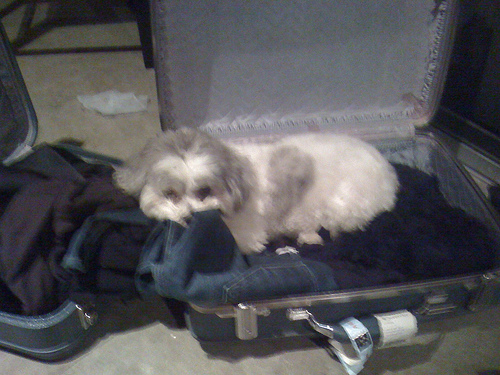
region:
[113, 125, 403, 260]
A little grey and white dog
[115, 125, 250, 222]
the head of a grey and white dog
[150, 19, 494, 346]
a suitcase with a dog and blue jeans in it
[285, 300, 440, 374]
the handle and tags of a suitcase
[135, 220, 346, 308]
a folded pair of blue jeans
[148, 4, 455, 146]
the top part of an open suitcase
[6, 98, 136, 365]
a portion of an open suitcase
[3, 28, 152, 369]
an open suitcase with dark clothing in it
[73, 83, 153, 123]
a tissue that has fallen on the floor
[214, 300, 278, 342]
a portion of a lock of an open suitcase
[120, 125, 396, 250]
the dog is resting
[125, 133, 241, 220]
the dog is looking at the viewer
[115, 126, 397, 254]
the dog is white and grey in color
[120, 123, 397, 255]
the dog is on top of a suitcase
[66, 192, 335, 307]
a pair of jeans is on the suitcase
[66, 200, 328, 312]
the jeans are blue in color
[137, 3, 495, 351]
the suitcase is open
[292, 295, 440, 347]
a handle is on the suitcase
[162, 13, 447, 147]
the suitcase has an inner lining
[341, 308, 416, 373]
tags are on the handle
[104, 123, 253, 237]
the head of a white dog.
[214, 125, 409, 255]
a dog on a mat.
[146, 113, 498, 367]
a piece of luggage on the ground.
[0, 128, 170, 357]
a half of a piece of luggage.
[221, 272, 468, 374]
a top of a piece of luggage.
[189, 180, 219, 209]
the left eye of a dog.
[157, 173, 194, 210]
the right eye of a dog.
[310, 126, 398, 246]
the back side of a dog.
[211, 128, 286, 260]
the front half of a dog.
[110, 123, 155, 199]
the right ear of a dog.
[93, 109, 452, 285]
a dog in the suitcase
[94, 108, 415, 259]
a white and gray dog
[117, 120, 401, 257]
Little dog sleeping in suitcase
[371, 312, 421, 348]
White luggage tag on handle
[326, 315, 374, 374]
Blue luggage tag on handle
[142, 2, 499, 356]
Large suitcase on floor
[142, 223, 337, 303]
Pair of jeans in suitcase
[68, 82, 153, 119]
White object on floor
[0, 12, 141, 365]
Blue suitcase on the floor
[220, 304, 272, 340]
Silver clasp on suitcase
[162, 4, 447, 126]
White cover on top of suitcase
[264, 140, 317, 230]
Grey spot on dog